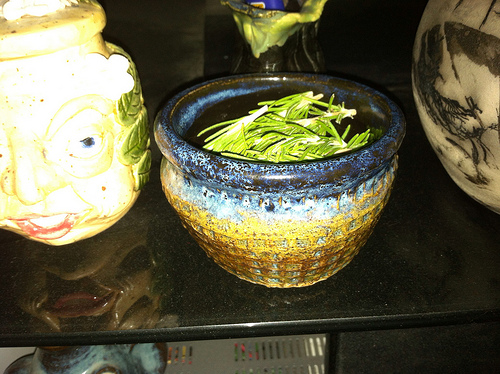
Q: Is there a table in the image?
A: Yes, there is a table.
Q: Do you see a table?
A: Yes, there is a table.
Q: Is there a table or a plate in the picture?
A: Yes, there is a table.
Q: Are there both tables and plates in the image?
A: No, there is a table but no plates.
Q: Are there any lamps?
A: No, there are no lamps.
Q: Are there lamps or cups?
A: No, there are no lamps or cups.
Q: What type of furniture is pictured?
A: The furniture is a table.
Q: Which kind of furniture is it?
A: The piece of furniture is a table.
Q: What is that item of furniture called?
A: This is a table.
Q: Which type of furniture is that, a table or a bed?
A: This is a table.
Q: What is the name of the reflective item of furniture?
A: The piece of furniture is a table.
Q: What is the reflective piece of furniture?
A: The piece of furniture is a table.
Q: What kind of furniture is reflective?
A: The furniture is a table.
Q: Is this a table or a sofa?
A: This is a table.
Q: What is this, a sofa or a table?
A: This is a table.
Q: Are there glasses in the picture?
A: No, there are no glasses.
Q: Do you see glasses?
A: No, there are no glasses.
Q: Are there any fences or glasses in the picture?
A: No, there are no glasses or fences.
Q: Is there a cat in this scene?
A: No, there are no cats.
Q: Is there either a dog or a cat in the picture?
A: No, there are no cats or dogs.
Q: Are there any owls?
A: Yes, there is an owl.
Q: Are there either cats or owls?
A: Yes, there is an owl.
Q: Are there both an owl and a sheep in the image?
A: No, there is an owl but no sheep.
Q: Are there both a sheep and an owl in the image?
A: No, there is an owl but no sheep.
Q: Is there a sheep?
A: No, there is no sheep.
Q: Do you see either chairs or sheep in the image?
A: No, there are no sheep or chairs.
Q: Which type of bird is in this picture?
A: The bird is an owl.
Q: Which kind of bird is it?
A: The bird is an owl.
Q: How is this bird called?
A: This is an owl.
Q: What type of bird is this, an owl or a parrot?
A: This is an owl.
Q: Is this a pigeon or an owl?
A: This is an owl.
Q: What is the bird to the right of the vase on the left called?
A: The bird is an owl.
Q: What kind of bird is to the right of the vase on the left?
A: The bird is an owl.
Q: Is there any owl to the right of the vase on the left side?
A: Yes, there is an owl to the right of the vase.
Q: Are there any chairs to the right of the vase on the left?
A: No, there is an owl to the right of the vase.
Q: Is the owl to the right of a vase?
A: Yes, the owl is to the right of a vase.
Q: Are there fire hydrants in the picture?
A: No, there are no fire hydrants.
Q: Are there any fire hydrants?
A: No, there are no fire hydrants.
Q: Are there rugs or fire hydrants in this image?
A: No, there are no fire hydrants or rugs.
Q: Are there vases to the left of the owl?
A: Yes, there is a vase to the left of the owl.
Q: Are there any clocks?
A: No, there are no clocks.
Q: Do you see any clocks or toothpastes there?
A: No, there are no clocks or toothpastes.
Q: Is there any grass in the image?
A: Yes, there is grass.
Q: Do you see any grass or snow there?
A: Yes, there is grass.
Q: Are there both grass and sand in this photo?
A: No, there is grass but no sand.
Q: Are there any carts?
A: No, there are no carts.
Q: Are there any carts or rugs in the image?
A: No, there are no carts or rugs.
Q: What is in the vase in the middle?
A: The grass is in the vase.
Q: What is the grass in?
A: The grass is in the vase.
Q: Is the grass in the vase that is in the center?
A: Yes, the grass is in the vase.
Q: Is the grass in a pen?
A: No, the grass is in the vase.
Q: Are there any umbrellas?
A: No, there are no umbrellas.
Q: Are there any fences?
A: No, there are no fences.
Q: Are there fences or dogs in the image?
A: No, there are no fences or dogs.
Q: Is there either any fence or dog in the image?
A: No, there are no fences or dogs.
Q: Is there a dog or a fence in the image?
A: No, there are no fences or dogs.